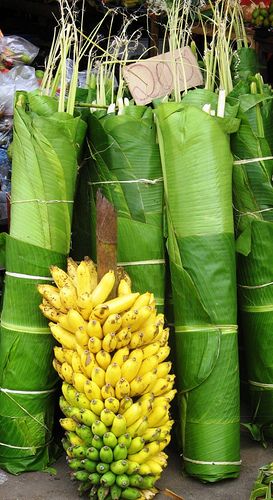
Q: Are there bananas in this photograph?
A: Yes, there is a banana.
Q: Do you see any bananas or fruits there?
A: Yes, there is a banana.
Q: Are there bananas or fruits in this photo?
A: Yes, there is a banana.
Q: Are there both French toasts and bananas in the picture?
A: No, there is a banana but no French toasts.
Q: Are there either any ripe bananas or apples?
A: Yes, there is a ripe banana.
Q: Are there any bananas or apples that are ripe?
A: Yes, the banana is ripe.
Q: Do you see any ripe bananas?
A: Yes, there is a ripe banana.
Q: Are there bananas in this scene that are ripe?
A: Yes, there is a banana that is ripe.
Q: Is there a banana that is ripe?
A: Yes, there is a banana that is ripe.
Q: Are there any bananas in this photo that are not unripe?
A: Yes, there is an ripe banana.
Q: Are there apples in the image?
A: No, there are no apples.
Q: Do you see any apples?
A: No, there are no apples.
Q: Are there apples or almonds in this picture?
A: No, there are no apples or almonds.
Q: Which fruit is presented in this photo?
A: The fruit is a banana.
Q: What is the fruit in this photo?
A: The fruit is a banana.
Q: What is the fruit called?
A: The fruit is a banana.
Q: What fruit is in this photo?
A: The fruit is a banana.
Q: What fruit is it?
A: The fruit is a banana.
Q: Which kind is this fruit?
A: This is a banana.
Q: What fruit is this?
A: This is a banana.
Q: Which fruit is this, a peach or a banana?
A: This is a banana.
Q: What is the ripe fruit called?
A: The fruit is a banana.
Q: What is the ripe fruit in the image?
A: The fruit is a banana.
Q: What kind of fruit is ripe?
A: The fruit is a banana.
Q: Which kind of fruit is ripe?
A: The fruit is a banana.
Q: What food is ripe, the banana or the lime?
A: The banana is ripe.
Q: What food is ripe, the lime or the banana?
A: The banana is ripe.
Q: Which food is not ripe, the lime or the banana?
A: The lime is not ripe.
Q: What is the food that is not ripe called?
A: The food is a lime.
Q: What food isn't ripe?
A: The food is a lime.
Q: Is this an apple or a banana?
A: This is a banana.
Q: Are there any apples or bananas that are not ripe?
A: No, there is a banana but it is ripe.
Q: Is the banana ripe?
A: Yes, the banana is ripe.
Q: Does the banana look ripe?
A: Yes, the banana is ripe.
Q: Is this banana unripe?
A: No, the banana is ripe.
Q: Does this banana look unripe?
A: No, the banana is ripe.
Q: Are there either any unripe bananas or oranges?
A: No, there is a banana but it is ripe.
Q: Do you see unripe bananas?
A: No, there is a banana but it is ripe.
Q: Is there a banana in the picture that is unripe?
A: No, there is a banana but it is ripe.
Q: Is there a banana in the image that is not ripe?
A: No, there is a banana but it is ripe.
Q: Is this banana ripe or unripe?
A: The banana is ripe.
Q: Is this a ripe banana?
A: Yes, this is a ripe banana.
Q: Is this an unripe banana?
A: No, this is a ripe banana.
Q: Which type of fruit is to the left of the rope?
A: The fruit is a banana.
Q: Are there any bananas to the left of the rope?
A: Yes, there is a banana to the left of the rope.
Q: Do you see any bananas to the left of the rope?
A: Yes, there is a banana to the left of the rope.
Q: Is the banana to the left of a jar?
A: No, the banana is to the left of the rope.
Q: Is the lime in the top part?
A: Yes, the lime is in the top of the image.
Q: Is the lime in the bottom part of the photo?
A: No, the lime is in the top of the image.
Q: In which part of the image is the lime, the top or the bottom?
A: The lime is in the top of the image.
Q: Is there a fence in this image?
A: No, there are no fences.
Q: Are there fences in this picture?
A: No, there are no fences.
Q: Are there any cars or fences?
A: No, there are no fences or cars.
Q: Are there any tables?
A: Yes, there is a table.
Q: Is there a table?
A: Yes, there is a table.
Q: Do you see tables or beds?
A: Yes, there is a table.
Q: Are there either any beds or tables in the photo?
A: Yes, there is a table.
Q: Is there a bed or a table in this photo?
A: Yes, there is a table.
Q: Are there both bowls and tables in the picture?
A: No, there is a table but no bowls.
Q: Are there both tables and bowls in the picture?
A: No, there is a table but no bowls.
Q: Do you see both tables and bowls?
A: No, there is a table but no bowls.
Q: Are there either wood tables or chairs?
A: Yes, there is a wood table.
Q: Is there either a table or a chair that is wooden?
A: Yes, the table is wooden.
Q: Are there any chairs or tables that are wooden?
A: Yes, the table is wooden.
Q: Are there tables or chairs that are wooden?
A: Yes, the table is wooden.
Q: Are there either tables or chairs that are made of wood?
A: Yes, the table is made of wood.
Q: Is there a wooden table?
A: Yes, there is a wood table.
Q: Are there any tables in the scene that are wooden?
A: Yes, there is a table that is wooden.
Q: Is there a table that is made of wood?
A: Yes, there is a table that is made of wood.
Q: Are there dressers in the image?
A: No, there are no dressers.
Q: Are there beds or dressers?
A: No, there are no dressers or beds.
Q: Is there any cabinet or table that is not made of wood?
A: No, there is a table but it is made of wood.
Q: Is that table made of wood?
A: Yes, the table is made of wood.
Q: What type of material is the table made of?
A: The table is made of wood.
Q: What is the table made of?
A: The table is made of wood.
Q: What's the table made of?
A: The table is made of wood.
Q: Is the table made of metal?
A: No, the table is made of wood.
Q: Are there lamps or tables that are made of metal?
A: No, there is a table but it is made of wood.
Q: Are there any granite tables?
A: No, there is a table but it is made of wood.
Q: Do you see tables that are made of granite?
A: No, there is a table but it is made of wood.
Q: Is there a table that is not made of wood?
A: No, there is a table but it is made of wood.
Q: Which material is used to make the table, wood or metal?
A: The table is made of wood.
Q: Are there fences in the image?
A: No, there are no fences.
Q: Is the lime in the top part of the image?
A: Yes, the lime is in the top of the image.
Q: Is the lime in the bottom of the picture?
A: No, the lime is in the top of the image.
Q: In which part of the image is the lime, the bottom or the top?
A: The lime is in the top of the image.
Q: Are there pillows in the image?
A: No, there are no pillows.